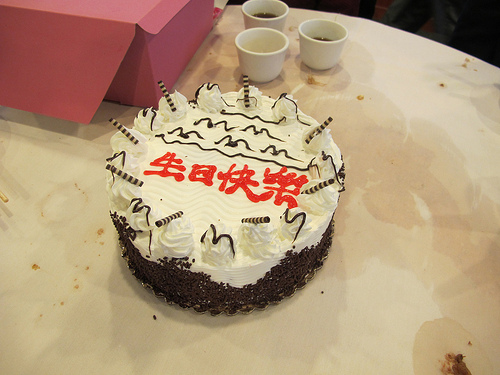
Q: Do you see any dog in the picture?
A: No, there are no dogs.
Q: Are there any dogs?
A: No, there are no dogs.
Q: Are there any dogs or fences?
A: No, there are no dogs or fences.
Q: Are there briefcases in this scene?
A: No, there are no briefcases.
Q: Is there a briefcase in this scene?
A: No, there are no briefcases.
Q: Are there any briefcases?
A: No, there are no briefcases.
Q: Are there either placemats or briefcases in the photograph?
A: No, there are no briefcases or placemats.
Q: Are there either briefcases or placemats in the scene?
A: No, there are no briefcases or placemats.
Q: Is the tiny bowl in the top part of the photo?
A: Yes, the bowl is in the top of the image.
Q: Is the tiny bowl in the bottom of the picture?
A: No, the bowl is in the top of the image.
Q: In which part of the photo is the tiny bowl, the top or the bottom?
A: The bowl is in the top of the image.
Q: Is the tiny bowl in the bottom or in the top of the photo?
A: The bowl is in the top of the image.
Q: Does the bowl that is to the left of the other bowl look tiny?
A: Yes, the bowl is tiny.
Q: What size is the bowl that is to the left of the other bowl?
A: The bowl is tiny.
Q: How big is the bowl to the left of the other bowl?
A: The bowl is tiny.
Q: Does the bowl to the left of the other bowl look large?
A: No, the bowl is tiny.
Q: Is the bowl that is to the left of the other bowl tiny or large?
A: The bowl is tiny.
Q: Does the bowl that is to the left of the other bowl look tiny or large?
A: The bowl is tiny.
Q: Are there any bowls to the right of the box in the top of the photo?
A: Yes, there is a bowl to the right of the box.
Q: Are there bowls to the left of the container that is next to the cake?
A: No, the bowl is to the right of the box.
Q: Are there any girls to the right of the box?
A: No, there is a bowl to the right of the box.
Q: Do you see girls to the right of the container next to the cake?
A: No, there is a bowl to the right of the box.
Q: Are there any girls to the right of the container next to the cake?
A: No, there is a bowl to the right of the box.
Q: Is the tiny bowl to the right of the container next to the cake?
A: Yes, the bowl is to the right of the box.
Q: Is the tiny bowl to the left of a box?
A: No, the bowl is to the right of a box.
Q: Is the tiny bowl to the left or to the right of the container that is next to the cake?
A: The bowl is to the right of the box.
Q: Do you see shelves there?
A: No, there are no shelves.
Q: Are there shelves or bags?
A: No, there are no shelves or bags.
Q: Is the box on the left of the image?
A: Yes, the box is on the left of the image.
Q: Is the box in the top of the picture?
A: Yes, the box is in the top of the image.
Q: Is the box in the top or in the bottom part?
A: The box is in the top of the image.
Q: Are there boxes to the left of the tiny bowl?
A: Yes, there is a box to the left of the bowl.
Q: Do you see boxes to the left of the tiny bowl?
A: Yes, there is a box to the left of the bowl.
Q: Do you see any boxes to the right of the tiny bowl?
A: No, the box is to the left of the bowl.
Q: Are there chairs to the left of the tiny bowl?
A: No, there is a box to the left of the bowl.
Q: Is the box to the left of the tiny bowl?
A: Yes, the box is to the left of the bowl.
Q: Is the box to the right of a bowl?
A: No, the box is to the left of a bowl.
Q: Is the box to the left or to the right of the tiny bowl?
A: The box is to the left of the bowl.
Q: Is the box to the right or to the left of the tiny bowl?
A: The box is to the left of the bowl.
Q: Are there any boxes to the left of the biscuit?
A: Yes, there is a box to the left of the biscuit.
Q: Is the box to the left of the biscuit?
A: Yes, the box is to the left of the biscuit.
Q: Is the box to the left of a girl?
A: No, the box is to the left of the biscuit.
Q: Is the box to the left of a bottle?
A: No, the box is to the left of a candle.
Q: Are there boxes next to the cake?
A: Yes, there is a box next to the cake.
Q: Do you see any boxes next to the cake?
A: Yes, there is a box next to the cake.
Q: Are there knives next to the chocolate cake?
A: No, there is a box next to the cake.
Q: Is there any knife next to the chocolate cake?
A: No, there is a box next to the cake.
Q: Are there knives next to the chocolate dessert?
A: No, there is a box next to the cake.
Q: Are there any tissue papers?
A: No, there are no tissue papers.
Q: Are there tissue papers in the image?
A: No, there are no tissue papers.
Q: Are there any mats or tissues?
A: No, there are no tissues or mats.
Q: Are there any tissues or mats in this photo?
A: No, there are no tissues or mats.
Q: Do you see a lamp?
A: No, there are no lamps.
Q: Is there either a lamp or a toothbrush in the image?
A: No, there are no lamps or toothbrushes.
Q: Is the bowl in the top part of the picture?
A: Yes, the bowl is in the top of the image.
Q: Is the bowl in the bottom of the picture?
A: No, the bowl is in the top of the image.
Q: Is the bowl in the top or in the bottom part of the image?
A: The bowl is in the top of the image.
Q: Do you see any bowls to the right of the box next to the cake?
A: Yes, there is a bowl to the right of the box.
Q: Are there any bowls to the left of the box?
A: No, the bowl is to the right of the box.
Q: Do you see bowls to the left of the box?
A: No, the bowl is to the right of the box.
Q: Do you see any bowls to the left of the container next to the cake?
A: No, the bowl is to the right of the box.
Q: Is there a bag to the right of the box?
A: No, there is a bowl to the right of the box.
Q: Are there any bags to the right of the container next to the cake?
A: No, there is a bowl to the right of the box.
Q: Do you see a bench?
A: No, there are no benches.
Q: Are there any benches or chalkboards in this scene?
A: No, there are no benches or chalkboards.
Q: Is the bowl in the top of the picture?
A: Yes, the bowl is in the top of the image.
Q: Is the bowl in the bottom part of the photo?
A: No, the bowl is in the top of the image.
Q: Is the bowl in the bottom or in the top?
A: The bowl is in the top of the image.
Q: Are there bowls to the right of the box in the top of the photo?
A: Yes, there is a bowl to the right of the box.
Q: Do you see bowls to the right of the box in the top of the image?
A: Yes, there is a bowl to the right of the box.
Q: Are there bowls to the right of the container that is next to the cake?
A: Yes, there is a bowl to the right of the box.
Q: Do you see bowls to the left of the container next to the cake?
A: No, the bowl is to the right of the box.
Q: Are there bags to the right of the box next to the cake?
A: No, there is a bowl to the right of the box.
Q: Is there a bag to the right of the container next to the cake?
A: No, there is a bowl to the right of the box.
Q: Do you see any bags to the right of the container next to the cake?
A: No, there is a bowl to the right of the box.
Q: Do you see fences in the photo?
A: No, there are no fences.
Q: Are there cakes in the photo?
A: Yes, there is a cake.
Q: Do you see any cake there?
A: Yes, there is a cake.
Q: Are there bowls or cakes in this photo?
A: Yes, there is a cake.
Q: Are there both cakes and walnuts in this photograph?
A: No, there is a cake but no walnuts.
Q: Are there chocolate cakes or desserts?
A: Yes, there is a chocolate cake.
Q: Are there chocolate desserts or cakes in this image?
A: Yes, there is a chocolate cake.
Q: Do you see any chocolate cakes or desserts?
A: Yes, there is a chocolate cake.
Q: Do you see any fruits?
A: No, there are no fruits.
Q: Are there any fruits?
A: No, there are no fruits.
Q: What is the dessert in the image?
A: The dessert is a cake.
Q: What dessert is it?
A: The dessert is a cake.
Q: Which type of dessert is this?
A: That is a cake.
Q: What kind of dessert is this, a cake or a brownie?
A: That is a cake.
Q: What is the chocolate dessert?
A: The dessert is a cake.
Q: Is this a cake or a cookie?
A: This is a cake.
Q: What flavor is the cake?
A: This is a chocolate cake.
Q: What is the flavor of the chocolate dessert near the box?
A: This is a chocolate cake.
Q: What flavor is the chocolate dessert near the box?
A: This is a chocolate cake.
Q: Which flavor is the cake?
A: This is a chocolate cake.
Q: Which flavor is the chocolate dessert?
A: This is a chocolate cake.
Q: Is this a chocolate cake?
A: Yes, this is a chocolate cake.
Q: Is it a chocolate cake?
A: Yes, this is a chocolate cake.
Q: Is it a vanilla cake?
A: No, this is a chocolate cake.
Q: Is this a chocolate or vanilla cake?
A: This is a chocolate cake.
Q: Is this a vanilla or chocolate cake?
A: This is a chocolate cake.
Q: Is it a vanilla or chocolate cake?
A: This is a chocolate cake.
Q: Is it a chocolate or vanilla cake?
A: This is a chocolate cake.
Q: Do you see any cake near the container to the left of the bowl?
A: Yes, there is a cake near the box.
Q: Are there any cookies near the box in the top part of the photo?
A: No, there is a cake near the box.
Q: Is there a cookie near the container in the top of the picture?
A: No, there is a cake near the box.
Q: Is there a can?
A: No, there are no cans.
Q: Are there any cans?
A: No, there are no cans.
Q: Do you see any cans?
A: No, there are no cans.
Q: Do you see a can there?
A: No, there are no cans.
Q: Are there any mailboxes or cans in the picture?
A: No, there are no cans or mailboxes.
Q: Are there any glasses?
A: No, there are no glasses.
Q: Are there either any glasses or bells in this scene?
A: No, there are no glasses or bells.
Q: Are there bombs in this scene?
A: No, there are no bombs.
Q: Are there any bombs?
A: No, there are no bombs.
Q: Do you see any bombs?
A: No, there are no bombs.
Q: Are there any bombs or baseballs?
A: No, there are no bombs or baseballs.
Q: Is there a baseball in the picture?
A: No, there are no baseballs.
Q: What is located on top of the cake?
A: The icing is on top of the cake.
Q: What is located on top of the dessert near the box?
A: The icing is on top of the cake.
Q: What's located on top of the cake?
A: The icing is on top of the cake.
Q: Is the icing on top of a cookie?
A: No, the icing is on top of a cake.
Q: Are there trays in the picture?
A: No, there are no trays.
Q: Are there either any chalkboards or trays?
A: No, there are no trays or chalkboards.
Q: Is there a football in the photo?
A: No, there are no footballs.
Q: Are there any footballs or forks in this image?
A: No, there are no footballs or forks.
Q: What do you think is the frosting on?
A: The frosting is on the cake.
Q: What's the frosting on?
A: The frosting is on the cake.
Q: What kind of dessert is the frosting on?
A: The frosting is on the cake.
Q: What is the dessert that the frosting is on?
A: The dessert is a cake.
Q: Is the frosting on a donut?
A: No, the frosting is on the cake.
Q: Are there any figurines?
A: No, there are no figurines.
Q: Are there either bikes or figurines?
A: No, there are no figurines or bikes.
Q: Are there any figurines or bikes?
A: No, there are no figurines or bikes.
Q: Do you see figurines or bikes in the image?
A: No, there are no figurines or bikes.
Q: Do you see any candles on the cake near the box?
A: Yes, there are candles on the cake.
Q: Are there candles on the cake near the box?
A: Yes, there are candles on the cake.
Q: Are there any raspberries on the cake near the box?
A: No, there are candles on the cake.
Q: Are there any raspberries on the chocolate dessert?
A: No, there are candles on the cake.